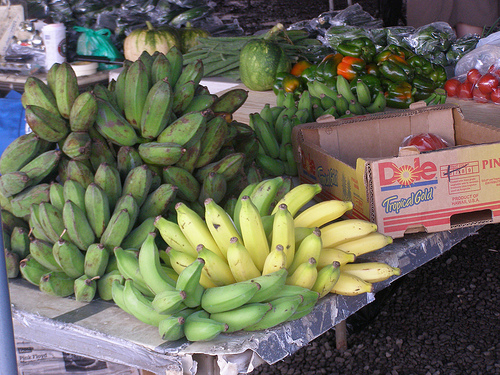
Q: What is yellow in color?
A: Bananas.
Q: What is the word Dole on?
A: Box.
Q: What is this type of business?
A: Fruit stand.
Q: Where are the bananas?
A: Up front.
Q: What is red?
A: Tomatoes.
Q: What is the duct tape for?
A: Table cloth.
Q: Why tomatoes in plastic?
A: Stay fresh.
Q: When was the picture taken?
A: Daytime.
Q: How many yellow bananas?
A: Nineteen.